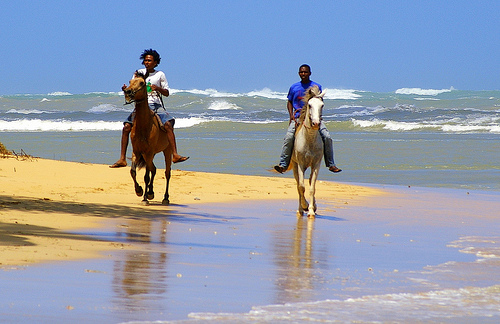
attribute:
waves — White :
[3, 83, 498, 133]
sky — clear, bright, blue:
[0, 0, 497, 92]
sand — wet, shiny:
[113, 207, 365, 292]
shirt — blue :
[284, 80, 320, 114]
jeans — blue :
[276, 118, 310, 165]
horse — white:
[288, 91, 326, 220]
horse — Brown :
[116, 75, 193, 227]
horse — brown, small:
[121, 81, 173, 187]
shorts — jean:
[119, 100, 180, 129]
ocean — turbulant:
[3, 84, 483, 163]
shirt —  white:
[138, 63, 176, 123]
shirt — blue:
[262, 69, 342, 119]